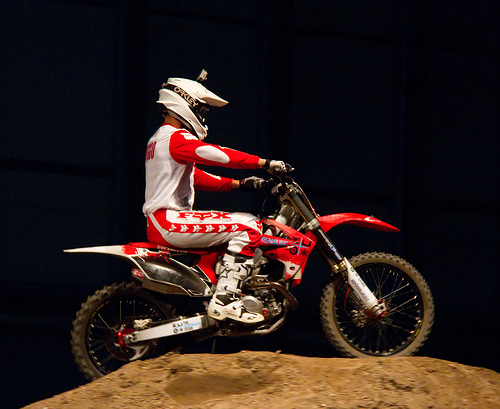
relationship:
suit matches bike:
[127, 112, 281, 334] [66, 57, 438, 388]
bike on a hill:
[62, 203, 453, 375] [13, 347, 497, 407]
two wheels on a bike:
[68, 255, 443, 375] [40, 195, 444, 385]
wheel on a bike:
[51, 274, 186, 391] [40, 195, 444, 385]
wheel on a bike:
[293, 237, 444, 365] [40, 195, 444, 385]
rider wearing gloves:
[143, 77, 288, 326] [271, 156, 296, 179]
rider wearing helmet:
[74, 47, 282, 353] [156, 0, 233, 64]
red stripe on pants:
[158, 220, 255, 235] [143, 204, 265, 276]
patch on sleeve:
[195, 142, 230, 167] [161, 128, 264, 176]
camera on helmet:
[178, 52, 235, 104] [157, 57, 227, 144]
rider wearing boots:
[143, 77, 288, 326] [207, 256, 266, 321]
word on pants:
[173, 197, 229, 229] [142, 208, 274, 269]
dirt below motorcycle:
[21, 350, 498, 407] [61, 74, 435, 380]